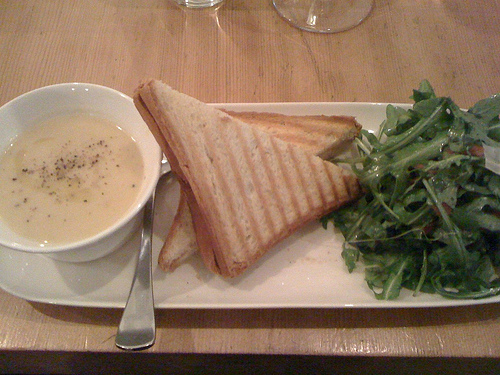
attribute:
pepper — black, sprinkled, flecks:
[9, 134, 137, 221]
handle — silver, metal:
[114, 183, 157, 350]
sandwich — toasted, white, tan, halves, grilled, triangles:
[130, 75, 361, 279]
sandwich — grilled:
[157, 106, 362, 275]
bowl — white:
[1, 79, 165, 262]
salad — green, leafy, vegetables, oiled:
[322, 77, 500, 300]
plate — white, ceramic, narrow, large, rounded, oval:
[1, 100, 499, 310]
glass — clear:
[271, 1, 371, 34]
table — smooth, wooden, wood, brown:
[1, 1, 499, 358]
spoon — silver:
[114, 154, 172, 351]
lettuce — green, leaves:
[321, 81, 499, 303]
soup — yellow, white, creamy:
[2, 115, 145, 242]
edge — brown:
[2, 348, 500, 374]